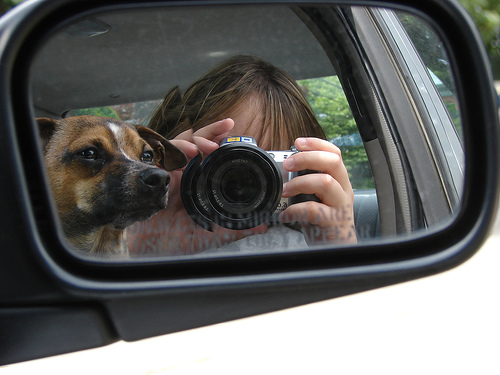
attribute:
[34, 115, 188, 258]
dog — looking, brown, black, handsome, focused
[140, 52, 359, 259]
girl — photographing, european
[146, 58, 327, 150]
hair — light, dark, brown, straight, thin, stringy, messy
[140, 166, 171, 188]
nose — black, cold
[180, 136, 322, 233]
camera — black, silver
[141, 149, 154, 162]
eye — black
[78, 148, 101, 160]
eye — black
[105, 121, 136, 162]
streak — white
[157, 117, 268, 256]
hand — manly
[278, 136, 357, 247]
hand — manly